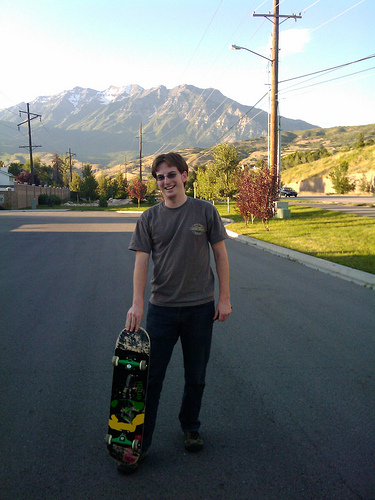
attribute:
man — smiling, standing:
[118, 152, 233, 475]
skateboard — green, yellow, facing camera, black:
[105, 328, 151, 468]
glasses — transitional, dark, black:
[155, 171, 180, 182]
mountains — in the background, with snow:
[1, 82, 323, 157]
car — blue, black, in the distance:
[279, 186, 298, 199]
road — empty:
[278, 189, 375, 215]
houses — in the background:
[1, 161, 24, 193]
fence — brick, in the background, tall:
[1, 179, 70, 212]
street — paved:
[2, 206, 374, 499]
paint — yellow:
[108, 413, 144, 434]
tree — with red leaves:
[255, 168, 280, 232]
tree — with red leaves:
[233, 167, 259, 227]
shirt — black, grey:
[128, 197, 226, 307]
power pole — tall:
[251, 1, 303, 201]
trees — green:
[9, 158, 128, 199]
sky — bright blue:
[2, 1, 374, 127]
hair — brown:
[151, 153, 188, 181]